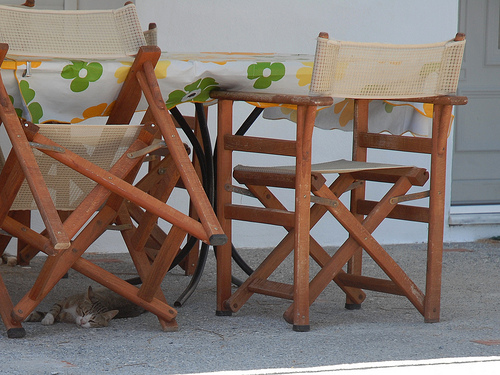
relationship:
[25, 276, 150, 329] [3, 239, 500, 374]
cat on ground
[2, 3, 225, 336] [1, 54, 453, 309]
chair against table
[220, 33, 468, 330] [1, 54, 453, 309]
chair at table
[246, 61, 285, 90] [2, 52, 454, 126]
flower on tablecloth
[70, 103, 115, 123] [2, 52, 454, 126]
flower on tablecloth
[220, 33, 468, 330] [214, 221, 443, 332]
chair has legs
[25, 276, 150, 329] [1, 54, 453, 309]
cat under table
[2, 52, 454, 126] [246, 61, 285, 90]
tablecloth has flower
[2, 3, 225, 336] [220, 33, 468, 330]
chair by chair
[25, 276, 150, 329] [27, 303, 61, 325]
cat has legs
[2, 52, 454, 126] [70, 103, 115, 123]
tablecloth has flower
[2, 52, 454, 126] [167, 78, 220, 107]
tablecloth has flower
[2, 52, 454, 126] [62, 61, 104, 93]
tablecloth has flower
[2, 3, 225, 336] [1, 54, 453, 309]
chair at table